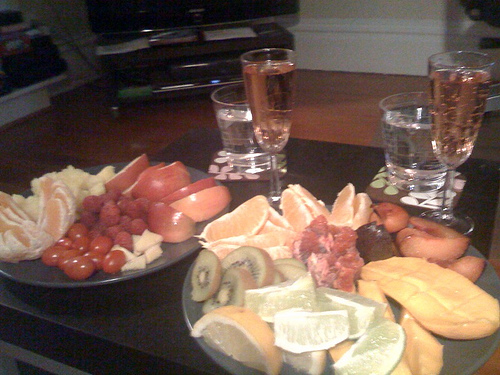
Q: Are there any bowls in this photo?
A: No, there are no bowls.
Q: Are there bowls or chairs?
A: No, there are no bowls or chairs.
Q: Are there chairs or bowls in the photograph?
A: No, there are no bowls or chairs.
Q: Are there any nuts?
A: No, there are no nuts.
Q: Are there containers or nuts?
A: No, there are no nuts or containers.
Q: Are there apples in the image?
A: Yes, there is an apple.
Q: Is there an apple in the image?
A: Yes, there is an apple.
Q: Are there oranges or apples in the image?
A: Yes, there is an apple.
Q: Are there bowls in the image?
A: No, there are no bowls.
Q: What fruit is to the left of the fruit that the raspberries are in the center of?
A: The fruit is an apple.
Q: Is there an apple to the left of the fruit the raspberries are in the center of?
A: Yes, there is an apple to the left of the fruit.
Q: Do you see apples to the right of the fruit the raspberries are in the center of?
A: No, the apple is to the left of the fruit.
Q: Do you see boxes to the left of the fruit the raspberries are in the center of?
A: No, there is an apple to the left of the fruit.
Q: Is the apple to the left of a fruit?
A: Yes, the apple is to the left of a fruit.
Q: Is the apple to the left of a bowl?
A: No, the apple is to the left of a fruit.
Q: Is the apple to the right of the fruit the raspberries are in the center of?
A: No, the apple is to the left of the fruit.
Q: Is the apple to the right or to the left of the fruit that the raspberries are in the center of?
A: The apple is to the left of the fruit.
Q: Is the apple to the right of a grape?
A: Yes, the apple is to the right of a grape.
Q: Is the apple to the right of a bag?
A: No, the apple is to the right of a grape.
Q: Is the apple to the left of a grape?
A: No, the apple is to the right of a grape.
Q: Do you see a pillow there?
A: No, there are no pillows.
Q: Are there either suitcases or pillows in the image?
A: No, there are no pillows or suitcases.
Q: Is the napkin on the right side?
A: Yes, the napkin is on the right of the image.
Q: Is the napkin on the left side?
A: No, the napkin is on the right of the image.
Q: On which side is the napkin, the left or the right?
A: The napkin is on the right of the image.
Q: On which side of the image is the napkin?
A: The napkin is on the right of the image.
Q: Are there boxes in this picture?
A: No, there are no boxes.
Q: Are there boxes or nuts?
A: No, there are no boxes or nuts.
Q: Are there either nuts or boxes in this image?
A: No, there are no boxes or nuts.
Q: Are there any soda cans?
A: No, there are no soda cans.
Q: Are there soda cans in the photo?
A: No, there are no soda cans.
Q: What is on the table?
A: The champagne is on the table.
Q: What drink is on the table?
A: The drink is champagne.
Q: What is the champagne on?
A: The champagne is on the table.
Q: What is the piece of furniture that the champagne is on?
A: The piece of furniture is a table.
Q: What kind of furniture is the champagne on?
A: The champagne is on the table.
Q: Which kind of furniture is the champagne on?
A: The champagne is on the table.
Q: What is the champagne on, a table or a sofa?
A: The champagne is on a table.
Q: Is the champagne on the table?
A: Yes, the champagne is on the table.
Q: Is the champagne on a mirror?
A: No, the champagne is on the table.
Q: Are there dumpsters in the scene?
A: No, there are no dumpsters.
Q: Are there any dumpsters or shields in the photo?
A: No, there are no dumpsters or shields.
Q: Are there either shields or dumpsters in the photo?
A: No, there are no dumpsters or shields.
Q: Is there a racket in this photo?
A: No, there are no rackets.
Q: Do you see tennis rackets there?
A: No, there are no tennis rackets.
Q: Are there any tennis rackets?
A: No, there are no tennis rackets.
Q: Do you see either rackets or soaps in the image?
A: No, there are no rackets or soaps.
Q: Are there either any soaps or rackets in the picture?
A: No, there are no rackets or soaps.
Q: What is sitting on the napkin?
A: The glass is sitting on the napkin.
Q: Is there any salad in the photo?
A: No, there is no salad.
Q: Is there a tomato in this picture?
A: Yes, there are tomatoes.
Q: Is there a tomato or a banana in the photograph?
A: Yes, there are tomatoes.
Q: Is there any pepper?
A: No, there are no peppers.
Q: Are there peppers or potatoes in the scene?
A: No, there are no peppers or potatoes.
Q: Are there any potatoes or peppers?
A: No, there are no peppers or potatoes.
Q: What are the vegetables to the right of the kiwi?
A: The vegetables are tomatoes.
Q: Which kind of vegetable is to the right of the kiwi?
A: The vegetables are tomatoes.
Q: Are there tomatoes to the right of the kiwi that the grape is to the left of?
A: Yes, there are tomatoes to the right of the kiwi.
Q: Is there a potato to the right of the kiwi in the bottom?
A: No, there are tomatoes to the right of the kiwi.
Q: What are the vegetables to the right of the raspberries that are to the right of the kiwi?
A: The vegetables are tomatoes.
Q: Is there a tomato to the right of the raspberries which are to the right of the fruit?
A: Yes, there are tomatoes to the right of the raspberries.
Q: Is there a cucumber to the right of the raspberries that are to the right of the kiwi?
A: No, there are tomatoes to the right of the raspberries.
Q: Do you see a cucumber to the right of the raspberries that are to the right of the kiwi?
A: No, there are tomatoes to the right of the raspberries.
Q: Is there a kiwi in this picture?
A: Yes, there is a kiwi.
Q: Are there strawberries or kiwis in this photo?
A: Yes, there is a kiwi.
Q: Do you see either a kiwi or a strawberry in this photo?
A: Yes, there is a kiwi.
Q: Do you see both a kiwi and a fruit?
A: Yes, there are both a kiwi and a fruit.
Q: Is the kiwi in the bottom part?
A: Yes, the kiwi is in the bottom of the image.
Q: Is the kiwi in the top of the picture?
A: No, the kiwi is in the bottom of the image.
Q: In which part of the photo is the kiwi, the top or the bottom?
A: The kiwi is in the bottom of the image.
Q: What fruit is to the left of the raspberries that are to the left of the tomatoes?
A: The fruit is a kiwi.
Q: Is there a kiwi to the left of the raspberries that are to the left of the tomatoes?
A: Yes, there is a kiwi to the left of the raspberries.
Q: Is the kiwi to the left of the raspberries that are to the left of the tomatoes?
A: Yes, the kiwi is to the left of the raspberries.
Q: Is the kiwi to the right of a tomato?
A: Yes, the kiwi is to the right of a tomato.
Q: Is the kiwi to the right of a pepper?
A: No, the kiwi is to the right of a tomato.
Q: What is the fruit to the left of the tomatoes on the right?
A: The fruit is a kiwi.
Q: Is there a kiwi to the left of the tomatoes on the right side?
A: Yes, there is a kiwi to the left of the tomatoes.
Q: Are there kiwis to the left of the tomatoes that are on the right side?
A: Yes, there is a kiwi to the left of the tomatoes.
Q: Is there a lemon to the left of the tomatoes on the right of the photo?
A: No, there is a kiwi to the left of the tomatoes.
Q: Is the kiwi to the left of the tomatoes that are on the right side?
A: Yes, the kiwi is to the left of the tomatoes.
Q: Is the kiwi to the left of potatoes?
A: No, the kiwi is to the left of the tomatoes.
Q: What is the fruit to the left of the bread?
A: The fruit is a kiwi.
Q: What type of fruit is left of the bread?
A: The fruit is a kiwi.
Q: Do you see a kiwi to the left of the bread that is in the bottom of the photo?
A: Yes, there is a kiwi to the left of the bread.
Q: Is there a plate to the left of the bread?
A: No, there is a kiwi to the left of the bread.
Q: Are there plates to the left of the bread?
A: No, there is a kiwi to the left of the bread.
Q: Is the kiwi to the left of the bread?
A: Yes, the kiwi is to the left of the bread.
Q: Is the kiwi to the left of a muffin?
A: No, the kiwi is to the left of the bread.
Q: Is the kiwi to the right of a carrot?
A: No, the kiwi is to the right of a tomato.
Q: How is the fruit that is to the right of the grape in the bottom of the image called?
A: The fruit is a kiwi.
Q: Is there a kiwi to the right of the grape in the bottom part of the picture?
A: Yes, there is a kiwi to the right of the grape.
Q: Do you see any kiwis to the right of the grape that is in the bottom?
A: Yes, there is a kiwi to the right of the grape.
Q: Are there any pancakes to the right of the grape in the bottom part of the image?
A: No, there is a kiwi to the right of the grape.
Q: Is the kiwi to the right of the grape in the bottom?
A: Yes, the kiwi is to the right of the grape.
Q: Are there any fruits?
A: Yes, there is a fruit.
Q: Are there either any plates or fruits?
A: Yes, there is a fruit.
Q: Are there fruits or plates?
A: Yes, there is a fruit.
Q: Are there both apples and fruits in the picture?
A: Yes, there are both a fruit and an apple.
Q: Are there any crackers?
A: No, there are no crackers.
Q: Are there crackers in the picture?
A: No, there are no crackers.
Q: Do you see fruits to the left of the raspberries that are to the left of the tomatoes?
A: Yes, there is a fruit to the left of the raspberries.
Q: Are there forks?
A: No, there are no forks.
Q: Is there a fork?
A: No, there are no forks.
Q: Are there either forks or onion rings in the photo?
A: No, there are no forks or onion rings.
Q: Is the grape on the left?
A: Yes, the grape is on the left of the image.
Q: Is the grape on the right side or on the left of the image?
A: The grape is on the left of the image.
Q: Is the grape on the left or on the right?
A: The grape is on the left of the image.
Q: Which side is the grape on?
A: The grape is on the left of the image.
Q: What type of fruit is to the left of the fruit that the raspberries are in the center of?
A: The fruit is a grape.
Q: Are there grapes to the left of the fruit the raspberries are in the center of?
A: Yes, there is a grape to the left of the fruit.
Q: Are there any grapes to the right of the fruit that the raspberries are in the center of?
A: No, the grape is to the left of the fruit.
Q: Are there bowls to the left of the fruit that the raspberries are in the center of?
A: No, there is a grape to the left of the fruit.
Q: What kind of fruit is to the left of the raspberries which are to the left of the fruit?
A: The fruit is a grape.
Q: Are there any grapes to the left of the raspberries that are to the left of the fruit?
A: Yes, there is a grape to the left of the raspberries.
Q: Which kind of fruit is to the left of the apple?
A: The fruit is a grape.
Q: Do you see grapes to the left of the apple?
A: Yes, there is a grape to the left of the apple.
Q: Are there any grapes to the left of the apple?
A: Yes, there is a grape to the left of the apple.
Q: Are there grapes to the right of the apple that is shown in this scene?
A: No, the grape is to the left of the apple.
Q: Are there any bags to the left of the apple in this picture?
A: No, there is a grape to the left of the apple.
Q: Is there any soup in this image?
A: No, there is no soup.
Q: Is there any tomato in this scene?
A: Yes, there is a tomato.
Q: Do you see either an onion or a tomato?
A: Yes, there is a tomato.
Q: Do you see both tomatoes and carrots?
A: No, there is a tomato but no carrots.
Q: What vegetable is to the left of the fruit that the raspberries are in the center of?
A: The vegetable is a tomato.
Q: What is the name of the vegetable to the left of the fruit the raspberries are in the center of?
A: The vegetable is a tomato.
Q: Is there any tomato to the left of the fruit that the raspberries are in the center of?
A: Yes, there is a tomato to the left of the fruit.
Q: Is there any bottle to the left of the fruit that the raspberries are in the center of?
A: No, there is a tomato to the left of the fruit.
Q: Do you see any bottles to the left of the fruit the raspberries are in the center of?
A: No, there is a tomato to the left of the fruit.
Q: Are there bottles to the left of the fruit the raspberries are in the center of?
A: No, there is a tomato to the left of the fruit.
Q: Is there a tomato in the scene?
A: Yes, there is a tomato.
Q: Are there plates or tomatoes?
A: Yes, there is a tomato.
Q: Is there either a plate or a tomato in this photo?
A: Yes, there is a tomato.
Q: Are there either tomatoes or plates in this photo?
A: Yes, there is a tomato.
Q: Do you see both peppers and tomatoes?
A: No, there is a tomato but no peppers.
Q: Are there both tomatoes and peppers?
A: No, there is a tomato but no peppers.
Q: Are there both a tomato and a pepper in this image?
A: No, there is a tomato but no peppers.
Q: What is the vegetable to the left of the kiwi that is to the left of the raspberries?
A: The vegetable is a tomato.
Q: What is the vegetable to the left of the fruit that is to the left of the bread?
A: The vegetable is a tomato.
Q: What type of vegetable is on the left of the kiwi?
A: The vegetable is a tomato.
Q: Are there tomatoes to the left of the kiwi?
A: Yes, there is a tomato to the left of the kiwi.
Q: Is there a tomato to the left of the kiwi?
A: Yes, there is a tomato to the left of the kiwi.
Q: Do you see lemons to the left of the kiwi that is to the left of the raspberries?
A: No, there is a tomato to the left of the kiwi.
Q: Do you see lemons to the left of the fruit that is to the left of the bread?
A: No, there is a tomato to the left of the kiwi.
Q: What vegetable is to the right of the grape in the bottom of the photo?
A: The vegetable is a tomato.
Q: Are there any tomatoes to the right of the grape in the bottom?
A: Yes, there is a tomato to the right of the grape.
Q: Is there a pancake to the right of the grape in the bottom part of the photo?
A: No, there is a tomato to the right of the grape.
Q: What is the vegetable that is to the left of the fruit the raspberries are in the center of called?
A: The vegetable is a tomato.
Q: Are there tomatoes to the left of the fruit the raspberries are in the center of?
A: Yes, there is a tomato to the left of the fruit.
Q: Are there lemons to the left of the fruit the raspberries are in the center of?
A: No, there is a tomato to the left of the fruit.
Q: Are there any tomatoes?
A: Yes, there is a tomato.